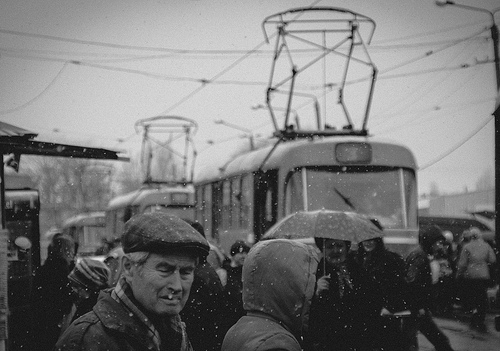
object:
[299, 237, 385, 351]
woman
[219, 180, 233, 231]
large window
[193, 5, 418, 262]
tram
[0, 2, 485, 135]
line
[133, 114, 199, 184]
electric lines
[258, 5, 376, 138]
electric lines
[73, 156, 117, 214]
electric lines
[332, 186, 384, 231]
wiper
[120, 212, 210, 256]
hat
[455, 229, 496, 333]
people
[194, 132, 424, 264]
bus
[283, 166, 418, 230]
glass windshield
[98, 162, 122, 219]
tree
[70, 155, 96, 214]
tree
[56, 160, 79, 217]
tree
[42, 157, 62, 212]
tree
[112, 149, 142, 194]
tree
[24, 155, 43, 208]
tree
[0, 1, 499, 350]
background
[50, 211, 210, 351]
gentleman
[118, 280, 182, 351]
scarf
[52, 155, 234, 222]
snow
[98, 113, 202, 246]
trams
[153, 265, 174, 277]
eyes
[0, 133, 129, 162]
awning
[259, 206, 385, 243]
open umbrella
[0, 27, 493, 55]
wires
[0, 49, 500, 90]
wires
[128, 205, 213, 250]
cap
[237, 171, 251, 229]
window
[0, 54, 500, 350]
station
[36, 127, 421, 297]
train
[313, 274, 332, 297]
hand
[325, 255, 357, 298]
scarf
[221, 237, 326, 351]
people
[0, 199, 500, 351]
passengers